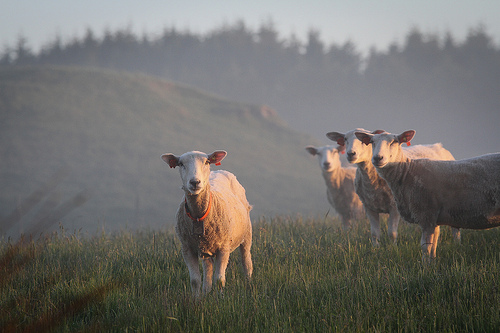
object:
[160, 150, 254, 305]
goat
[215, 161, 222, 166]
tag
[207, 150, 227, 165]
ear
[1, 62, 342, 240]
hill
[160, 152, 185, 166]
ears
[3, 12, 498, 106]
trees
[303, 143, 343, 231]
sheep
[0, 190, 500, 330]
grass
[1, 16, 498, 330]
field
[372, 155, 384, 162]
noses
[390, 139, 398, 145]
eyes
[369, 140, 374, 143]
eyes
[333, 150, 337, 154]
eyes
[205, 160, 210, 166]
eyes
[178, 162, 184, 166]
eyes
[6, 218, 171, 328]
branches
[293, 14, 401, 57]
sky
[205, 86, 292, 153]
rock formation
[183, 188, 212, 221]
collar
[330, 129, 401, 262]
cows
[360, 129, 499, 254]
goats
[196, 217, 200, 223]
bell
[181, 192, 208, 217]
neck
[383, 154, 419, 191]
neck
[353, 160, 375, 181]
neck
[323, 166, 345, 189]
neck